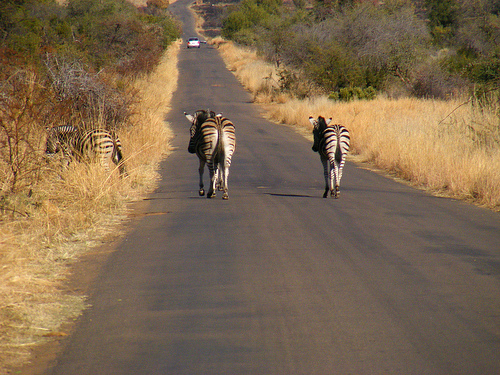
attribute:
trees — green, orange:
[2, 0, 179, 111]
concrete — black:
[50, 2, 497, 370]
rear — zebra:
[201, 117, 239, 158]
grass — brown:
[11, 142, 130, 301]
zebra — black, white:
[303, 112, 352, 199]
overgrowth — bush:
[259, 6, 498, 103]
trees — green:
[288, 7, 466, 104]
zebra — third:
[44, 122, 122, 169]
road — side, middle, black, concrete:
[51, 0, 499, 375]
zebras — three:
[43, 110, 350, 202]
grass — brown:
[0, 30, 190, 370]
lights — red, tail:
[184, 40, 204, 47]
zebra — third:
[34, 105, 138, 199]